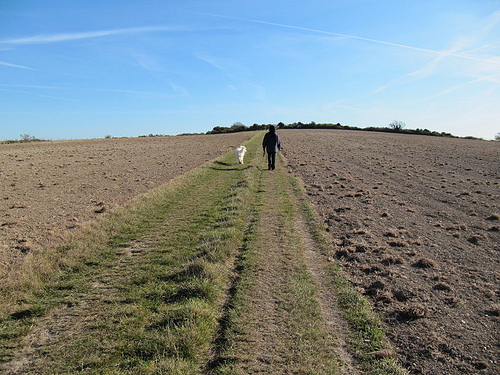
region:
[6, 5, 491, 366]
person walking with dog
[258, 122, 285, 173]
back of a person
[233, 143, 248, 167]
back of a dog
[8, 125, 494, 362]
a large barren field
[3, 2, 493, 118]
blue sky with a few clouds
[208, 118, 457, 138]
trees and brush near field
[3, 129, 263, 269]
left side of barren field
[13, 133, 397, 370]
grassy strip in middle of field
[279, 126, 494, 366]
right side of barren field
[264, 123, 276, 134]
back of person's head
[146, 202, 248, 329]
grasses are on the road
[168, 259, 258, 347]
grasse are green in color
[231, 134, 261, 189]
the dog isw alking beside he man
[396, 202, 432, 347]
the land is ploughedt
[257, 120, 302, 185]
the amn is dressed in black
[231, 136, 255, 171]
the dog is white in color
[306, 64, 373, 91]
the sky is coverd of clouds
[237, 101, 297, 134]
trees are seen at th background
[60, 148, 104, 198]
the land is coverd of soil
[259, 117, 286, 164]
man walking on grass road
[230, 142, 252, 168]
white animal walking with man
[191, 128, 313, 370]
green road in dirt field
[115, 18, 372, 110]
bright blue sky above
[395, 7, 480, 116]
white clouds in blue sky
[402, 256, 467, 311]
dirt clumps in field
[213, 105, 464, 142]
trees growing in the distance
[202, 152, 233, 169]
shadow of white animal on field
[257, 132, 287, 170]
black outfit of man walking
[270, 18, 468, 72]
jet contrail in sky above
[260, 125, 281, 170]
A person walks in a field.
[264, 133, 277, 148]
The person is wearing black.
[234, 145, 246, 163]
A dog is with the person.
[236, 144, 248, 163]
The dog is white.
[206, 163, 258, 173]
The person's shadow is on the ground.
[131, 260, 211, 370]
Grass grows along the path.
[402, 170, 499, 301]
The ground is made of dirt.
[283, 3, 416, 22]
The sky is blue.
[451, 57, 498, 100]
Clouds are in the sky.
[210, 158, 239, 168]
The dog's shadow is on the ground.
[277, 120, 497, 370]
dry field at right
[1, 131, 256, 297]
dry field at left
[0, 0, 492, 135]
blue sky with no clouds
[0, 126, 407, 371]
grass in the middle of the field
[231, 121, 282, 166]
person walking on grass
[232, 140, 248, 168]
white dog beside person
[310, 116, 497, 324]
clumps of dirt and dry grass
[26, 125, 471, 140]
trees and shrubs along the horizon line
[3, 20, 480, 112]
whispy white lines in sky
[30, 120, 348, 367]
a worn track from driving on the grass